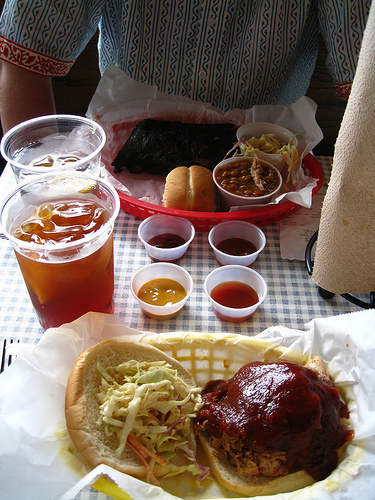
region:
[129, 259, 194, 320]
a dish of mustard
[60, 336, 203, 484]
the top of a bun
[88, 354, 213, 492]
coleslaw on the bun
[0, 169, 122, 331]
a cup on the table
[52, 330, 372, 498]
a yellow basket on the table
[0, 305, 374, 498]
a white paper in the basket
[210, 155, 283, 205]
a dish of beans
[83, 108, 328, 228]
a red plastic basket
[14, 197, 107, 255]
ice in the cup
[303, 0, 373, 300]
a paper towel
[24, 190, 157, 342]
brown liquid in cup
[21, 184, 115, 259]
ice is in cup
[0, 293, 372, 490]
paper wrapper in the basket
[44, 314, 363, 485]
the basket is yellow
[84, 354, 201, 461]
cole slaw on the bread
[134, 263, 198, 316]
mustard in the cup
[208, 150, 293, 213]
pork n beans in the cup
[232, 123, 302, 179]
cole slaw in the cup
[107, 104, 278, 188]
meat on person's tray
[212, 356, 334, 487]
barbecue sauce on the bun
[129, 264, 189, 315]
the yellow sauce in the small container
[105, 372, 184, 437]
the cabbage on the bread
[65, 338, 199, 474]
the top of the hamburger bun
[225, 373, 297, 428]
the sauce on the meat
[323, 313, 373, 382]
the paper under the sandwich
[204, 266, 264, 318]
the sauce in the container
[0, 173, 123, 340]
the cup filled with liquid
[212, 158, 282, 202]
the container filled with beans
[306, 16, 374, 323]
the brown paper towel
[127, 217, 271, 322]
the four small containers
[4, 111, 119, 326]
Cold drinks sitting on a table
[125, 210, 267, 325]
Sauces in cups for a meal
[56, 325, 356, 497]
Open face sandwich ready to eat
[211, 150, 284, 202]
Beans in a plastic cup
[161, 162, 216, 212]
Dinner roll ready to eat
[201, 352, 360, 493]
Barbecue sauce on a sandwich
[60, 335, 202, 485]
Shredded lettuce on a sandwich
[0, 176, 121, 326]
Cold iced tea in a plastic cup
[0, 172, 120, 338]
Cold drink with ice in it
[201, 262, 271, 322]
Red sauce in a plastic cup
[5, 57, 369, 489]
A restaurant table scene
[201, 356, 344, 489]
This is a barbaque sandwich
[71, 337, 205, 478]
A sandwich bun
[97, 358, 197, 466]
Coleslaw is on the bun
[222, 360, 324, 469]
The sandwich is covered in sauce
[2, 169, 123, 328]
A glass of iced tea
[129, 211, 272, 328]
Cups with dipping sauces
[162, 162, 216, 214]
A bread roll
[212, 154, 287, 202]
This is a cup of beans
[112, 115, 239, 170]
These are barbecued ribs